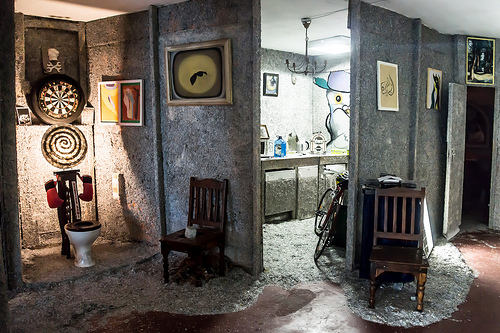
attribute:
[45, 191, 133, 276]
toilet — one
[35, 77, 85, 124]
board — dart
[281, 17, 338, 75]
chandelier — brown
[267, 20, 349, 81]
light — one, hanging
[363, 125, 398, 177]
wall — one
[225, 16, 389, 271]
door way — one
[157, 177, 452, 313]
chairs — brown, dark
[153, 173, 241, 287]
chair — wooden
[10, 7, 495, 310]
picture — red, yellow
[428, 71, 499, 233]
door — one, open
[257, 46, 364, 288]
door — grey